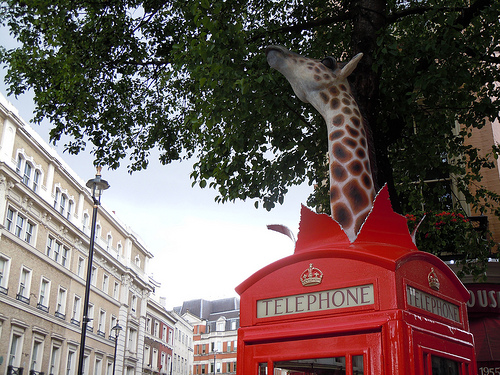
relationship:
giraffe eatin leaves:
[261, 37, 396, 245] [248, 51, 276, 82]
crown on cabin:
[296, 261, 326, 288] [229, 178, 480, 374]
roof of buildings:
[167, 292, 242, 320] [169, 293, 252, 375]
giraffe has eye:
[261, 37, 396, 245] [317, 55, 339, 76]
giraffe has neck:
[261, 37, 396, 245] [311, 93, 385, 245]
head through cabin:
[262, 37, 367, 111] [229, 178, 480, 374]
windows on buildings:
[14, 148, 46, 194] [0, 92, 157, 374]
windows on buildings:
[50, 183, 75, 226] [0, 92, 157, 374]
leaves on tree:
[248, 51, 276, 82] [1, 1, 500, 290]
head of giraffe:
[262, 37, 367, 111] [261, 37, 396, 245]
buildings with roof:
[169, 293, 252, 375] [167, 292, 242, 320]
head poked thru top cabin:
[262, 37, 367, 111] [229, 178, 480, 374]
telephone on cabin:
[254, 284, 378, 321] [229, 178, 480, 374]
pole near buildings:
[70, 163, 110, 375] [0, 92, 157, 374]